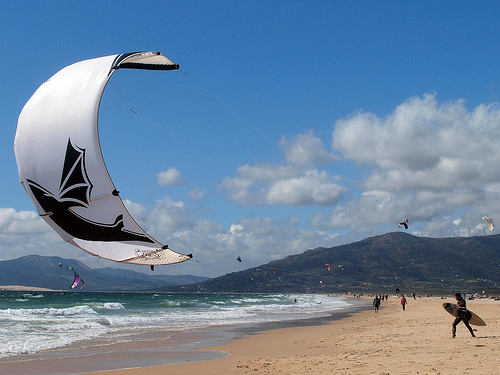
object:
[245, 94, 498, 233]
cloud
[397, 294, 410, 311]
woman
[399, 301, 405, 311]
pants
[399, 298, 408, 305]
shirt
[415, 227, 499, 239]
wind farm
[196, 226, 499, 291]
hill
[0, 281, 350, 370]
sea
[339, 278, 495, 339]
people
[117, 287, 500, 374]
shore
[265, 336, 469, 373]
footprints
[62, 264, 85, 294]
windsail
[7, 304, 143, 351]
waves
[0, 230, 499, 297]
hills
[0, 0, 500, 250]
sky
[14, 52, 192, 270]
kite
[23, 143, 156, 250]
image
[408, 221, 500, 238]
windmills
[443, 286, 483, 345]
person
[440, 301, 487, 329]
surfboard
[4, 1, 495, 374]
beach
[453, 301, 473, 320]
wetsuit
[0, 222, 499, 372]
land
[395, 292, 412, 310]
person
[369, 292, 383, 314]
person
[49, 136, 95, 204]
fins